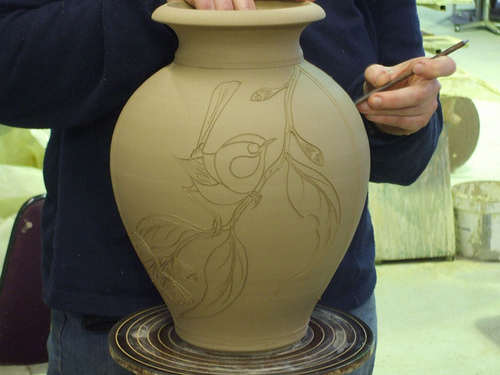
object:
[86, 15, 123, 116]
wrinkle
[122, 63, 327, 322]
branch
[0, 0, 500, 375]
table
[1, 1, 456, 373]
man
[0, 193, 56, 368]
chair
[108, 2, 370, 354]
pot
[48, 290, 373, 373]
jeans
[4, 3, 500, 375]
photo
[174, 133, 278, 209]
bird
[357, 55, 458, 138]
hand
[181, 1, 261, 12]
hand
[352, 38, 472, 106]
tool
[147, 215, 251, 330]
leaves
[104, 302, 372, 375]
potter's wheel